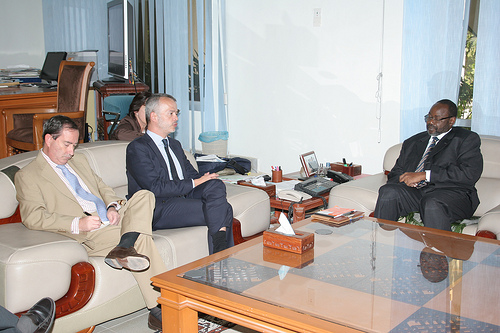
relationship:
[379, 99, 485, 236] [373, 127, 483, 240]
man in suit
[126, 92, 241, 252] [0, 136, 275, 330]
man on couch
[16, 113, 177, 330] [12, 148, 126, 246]
man wearing jacket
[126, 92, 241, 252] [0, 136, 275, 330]
man on a couch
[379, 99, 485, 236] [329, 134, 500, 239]
man in a chair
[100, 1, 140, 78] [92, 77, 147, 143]
tv on top of stand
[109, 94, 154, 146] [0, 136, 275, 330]
lady behind couch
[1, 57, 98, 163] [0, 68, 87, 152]
chair around desk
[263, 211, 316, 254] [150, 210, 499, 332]
box on top of table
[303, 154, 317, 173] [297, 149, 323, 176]
picture in a frame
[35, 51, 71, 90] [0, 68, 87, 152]
computer on top of desk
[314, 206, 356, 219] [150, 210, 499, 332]
notepad on top of table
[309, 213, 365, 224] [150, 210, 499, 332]
planner on top of table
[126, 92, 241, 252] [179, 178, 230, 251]
man crossing leg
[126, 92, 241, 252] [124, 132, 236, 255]
man wearing suit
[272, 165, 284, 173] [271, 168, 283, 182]
pens in pot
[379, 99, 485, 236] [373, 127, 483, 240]
man wearing suit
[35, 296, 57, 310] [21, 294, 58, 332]
tip of shoe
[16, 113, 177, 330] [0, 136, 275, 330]
man on a couch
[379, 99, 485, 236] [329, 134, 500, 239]
man in armchair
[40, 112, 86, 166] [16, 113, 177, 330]
head of a man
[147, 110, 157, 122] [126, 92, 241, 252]
ear of a man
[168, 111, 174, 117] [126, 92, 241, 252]
eye of a man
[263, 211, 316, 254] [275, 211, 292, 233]
box of tissue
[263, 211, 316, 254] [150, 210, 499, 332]
box on table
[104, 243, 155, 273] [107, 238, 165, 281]
shoe on foot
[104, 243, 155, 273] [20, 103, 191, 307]
shoe on man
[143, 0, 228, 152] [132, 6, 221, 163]
blinds over window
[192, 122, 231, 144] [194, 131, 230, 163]
garbage bag in trash can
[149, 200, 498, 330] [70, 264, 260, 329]
coffee table in middle of floor